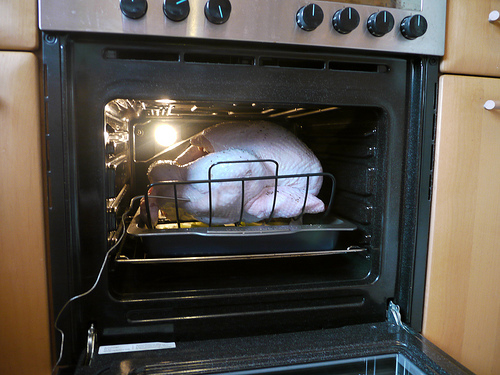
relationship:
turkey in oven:
[135, 118, 326, 224] [39, 34, 437, 334]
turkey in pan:
[135, 118, 326, 224] [125, 203, 355, 252]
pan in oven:
[125, 203, 355, 252] [39, 34, 437, 334]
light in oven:
[152, 124, 181, 152] [39, 34, 437, 334]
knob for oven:
[298, 3, 324, 32] [39, 34, 437, 334]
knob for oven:
[332, 7, 358, 34] [39, 34, 437, 334]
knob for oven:
[369, 9, 395, 37] [39, 34, 437, 334]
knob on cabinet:
[484, 98, 498, 111] [417, 74, 493, 372]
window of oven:
[226, 357, 417, 374] [39, 34, 437, 334]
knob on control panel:
[298, 3, 324, 32] [37, 1, 446, 55]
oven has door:
[39, 34, 437, 334] [72, 323, 469, 374]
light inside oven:
[152, 124, 181, 152] [39, 34, 437, 334]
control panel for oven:
[37, 1, 446, 55] [39, 34, 437, 334]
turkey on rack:
[135, 118, 326, 224] [139, 160, 334, 222]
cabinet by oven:
[417, 74, 493, 372] [39, 34, 437, 334]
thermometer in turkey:
[128, 193, 190, 205] [135, 118, 326, 224]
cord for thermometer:
[53, 196, 138, 366] [128, 193, 190, 205]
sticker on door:
[98, 341, 177, 354] [72, 323, 469, 374]